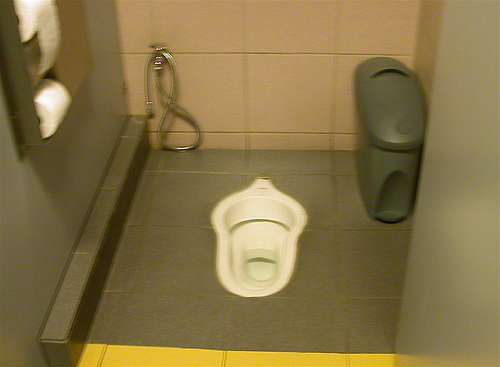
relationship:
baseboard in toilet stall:
[36, 112, 153, 365] [4, 1, 484, 365]